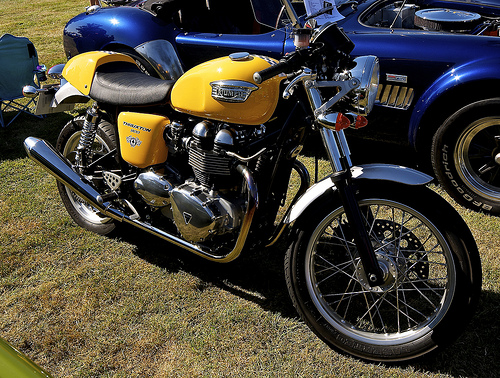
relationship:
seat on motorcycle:
[97, 70, 171, 100] [47, 46, 489, 358]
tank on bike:
[173, 53, 284, 123] [47, 46, 489, 358]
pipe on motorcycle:
[18, 138, 102, 206] [47, 46, 489, 358]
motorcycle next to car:
[47, 46, 489, 358] [63, 5, 497, 52]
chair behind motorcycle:
[3, 32, 42, 132] [47, 46, 489, 358]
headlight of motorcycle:
[353, 58, 385, 116] [47, 46, 489, 358]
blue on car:
[85, 12, 161, 34] [63, 5, 497, 52]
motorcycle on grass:
[47, 46, 489, 358] [17, 227, 91, 275]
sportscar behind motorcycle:
[63, 5, 497, 52] [47, 46, 489, 358]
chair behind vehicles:
[3, 32, 42, 132] [47, 46, 489, 358]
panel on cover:
[213, 82, 257, 103] [173, 53, 284, 123]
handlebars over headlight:
[255, 51, 324, 85] [353, 58, 385, 116]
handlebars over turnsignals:
[255, 51, 324, 85] [322, 116, 368, 129]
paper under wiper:
[310, 6, 345, 24] [301, 2, 349, 20]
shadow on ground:
[122, 245, 171, 273] [84, 272, 198, 344]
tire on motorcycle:
[280, 175, 478, 359] [47, 46, 489, 358]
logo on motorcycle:
[213, 82, 257, 103] [47, 46, 489, 358]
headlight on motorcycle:
[353, 58, 385, 116] [47, 46, 489, 358]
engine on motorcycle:
[195, 125, 249, 195] [47, 46, 489, 358]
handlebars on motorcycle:
[255, 51, 324, 85] [47, 46, 489, 358]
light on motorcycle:
[21, 86, 40, 99] [47, 46, 489, 358]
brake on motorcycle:
[347, 246, 414, 297] [47, 46, 489, 358]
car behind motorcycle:
[63, 5, 497, 52] [47, 46, 489, 358]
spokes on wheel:
[337, 276, 393, 315] [418, 19, 480, 32]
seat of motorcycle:
[97, 70, 171, 100] [47, 46, 489, 358]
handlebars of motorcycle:
[255, 51, 324, 85] [47, 46, 489, 358]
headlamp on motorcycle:
[353, 58, 385, 116] [47, 46, 489, 358]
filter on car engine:
[417, 7, 489, 31] [375, 1, 498, 39]